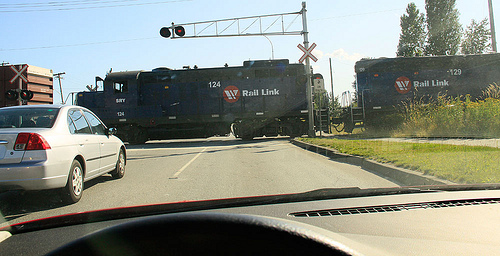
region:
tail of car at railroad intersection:
[2, 130, 127, 187]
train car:
[91, 75, 307, 126]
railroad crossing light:
[284, 6, 339, 137]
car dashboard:
[198, 216, 499, 250]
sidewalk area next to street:
[339, 119, 496, 186]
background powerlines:
[57, 69, 82, 94]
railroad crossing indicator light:
[4, 60, 36, 105]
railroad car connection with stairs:
[316, 105, 371, 131]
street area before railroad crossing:
[162, 137, 300, 185]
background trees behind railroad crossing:
[390, 16, 488, 56]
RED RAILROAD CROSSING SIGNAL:
[154, 21, 189, 41]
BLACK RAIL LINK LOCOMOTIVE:
[73, 56, 332, 143]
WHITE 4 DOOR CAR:
[1, 98, 128, 200]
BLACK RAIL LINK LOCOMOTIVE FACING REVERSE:
[345, 53, 499, 122]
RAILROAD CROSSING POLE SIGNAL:
[6, 62, 35, 106]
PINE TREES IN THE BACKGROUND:
[394, 0, 486, 54]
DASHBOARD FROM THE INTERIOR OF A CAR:
[11, 189, 499, 254]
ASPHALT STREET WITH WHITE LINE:
[130, 147, 318, 196]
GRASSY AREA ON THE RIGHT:
[311, 133, 498, 178]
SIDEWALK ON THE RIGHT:
[361, 132, 498, 148]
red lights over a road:
[160, 19, 315, 45]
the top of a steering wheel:
[57, 214, 358, 250]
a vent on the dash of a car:
[312, 194, 494, 225]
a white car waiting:
[4, 105, 132, 185]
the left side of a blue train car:
[122, 63, 315, 128]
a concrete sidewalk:
[371, 131, 496, 165]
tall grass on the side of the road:
[410, 91, 497, 120]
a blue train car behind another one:
[365, 56, 498, 102]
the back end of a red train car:
[1, 54, 58, 99]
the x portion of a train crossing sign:
[292, 37, 320, 64]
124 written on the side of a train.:
[201, 77, 226, 92]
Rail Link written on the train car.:
[241, 85, 283, 100]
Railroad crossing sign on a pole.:
[293, 42, 323, 69]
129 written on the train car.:
[441, 66, 473, 81]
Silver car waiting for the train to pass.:
[3, 99, 135, 201]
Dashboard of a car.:
[13, 197, 483, 254]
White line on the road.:
[160, 143, 224, 184]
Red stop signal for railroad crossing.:
[153, 14, 315, 42]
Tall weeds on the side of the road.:
[409, 95, 499, 146]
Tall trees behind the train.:
[396, 5, 493, 50]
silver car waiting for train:
[2, 103, 131, 204]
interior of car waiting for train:
[5, 180, 485, 253]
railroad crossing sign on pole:
[295, 41, 319, 68]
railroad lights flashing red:
[152, 18, 192, 44]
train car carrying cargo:
[345, 54, 499, 119]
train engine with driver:
[70, 57, 307, 139]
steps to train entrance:
[314, 96, 334, 134]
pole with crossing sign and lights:
[5, 60, 32, 100]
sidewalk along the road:
[316, 132, 492, 148]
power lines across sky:
[0, 0, 498, 57]